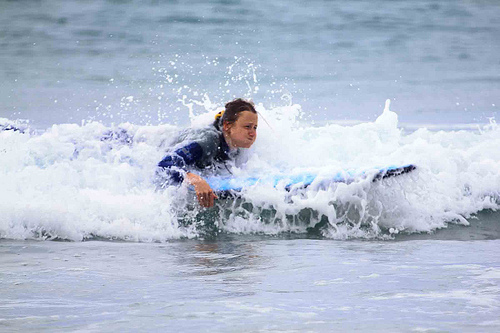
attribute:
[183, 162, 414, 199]
surfboard — aqua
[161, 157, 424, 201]
board — blue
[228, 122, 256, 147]
cheeks — puffed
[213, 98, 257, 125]
hair — brown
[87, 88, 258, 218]
woman — wet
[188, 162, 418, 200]
surf board — blue, two toned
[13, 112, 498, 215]
waves — white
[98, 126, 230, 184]
wetsuit — blue